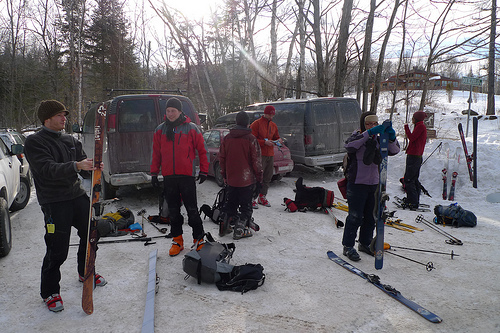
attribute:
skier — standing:
[28, 96, 110, 312]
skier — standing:
[145, 87, 215, 257]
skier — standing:
[214, 107, 268, 245]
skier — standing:
[338, 112, 408, 264]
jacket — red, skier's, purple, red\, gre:
[149, 115, 211, 183]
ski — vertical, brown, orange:
[79, 99, 118, 313]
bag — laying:
[176, 233, 270, 297]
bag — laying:
[284, 173, 342, 214]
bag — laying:
[432, 201, 482, 230]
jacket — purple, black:
[341, 115, 404, 183]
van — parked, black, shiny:
[246, 85, 369, 178]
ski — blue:
[369, 120, 391, 271]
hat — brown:
[36, 97, 69, 123]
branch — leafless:
[264, 0, 295, 43]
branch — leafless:
[366, 7, 421, 53]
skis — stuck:
[458, 114, 484, 189]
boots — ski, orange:
[169, 233, 215, 258]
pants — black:
[160, 174, 201, 238]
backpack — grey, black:
[181, 231, 281, 297]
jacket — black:
[21, 126, 93, 207]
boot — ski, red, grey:
[259, 198, 276, 209]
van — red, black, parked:
[80, 88, 205, 190]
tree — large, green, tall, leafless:
[75, 2, 149, 129]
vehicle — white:
[0, 132, 33, 256]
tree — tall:
[333, 0, 364, 97]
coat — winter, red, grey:
[148, 113, 215, 180]